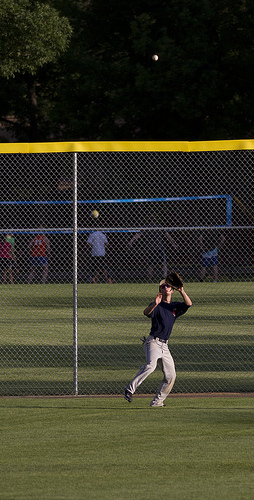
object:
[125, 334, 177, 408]
pants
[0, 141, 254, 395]
fence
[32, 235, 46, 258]
shirt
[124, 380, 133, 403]
foot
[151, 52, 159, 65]
ball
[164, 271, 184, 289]
mitt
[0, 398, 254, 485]
grass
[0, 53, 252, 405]
park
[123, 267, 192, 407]
man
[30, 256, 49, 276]
shorts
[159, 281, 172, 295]
face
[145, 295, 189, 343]
shirt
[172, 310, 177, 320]
logo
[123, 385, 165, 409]
shoes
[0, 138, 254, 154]
marker